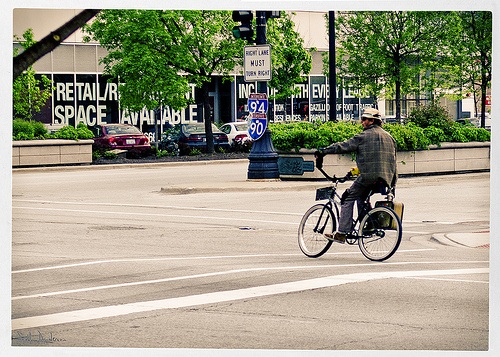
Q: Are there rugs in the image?
A: No, there are no rugs.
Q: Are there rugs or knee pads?
A: No, there are no rugs or knee pads.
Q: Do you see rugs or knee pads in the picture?
A: No, there are no rugs or knee pads.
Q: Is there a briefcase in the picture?
A: Yes, there is a briefcase.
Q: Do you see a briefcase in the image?
A: Yes, there is a briefcase.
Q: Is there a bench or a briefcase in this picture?
A: Yes, there is a briefcase.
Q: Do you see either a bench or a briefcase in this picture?
A: Yes, there is a briefcase.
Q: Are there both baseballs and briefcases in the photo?
A: No, there is a briefcase but no baseballs.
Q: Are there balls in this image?
A: No, there are no balls.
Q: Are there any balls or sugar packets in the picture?
A: No, there are no balls or sugar packets.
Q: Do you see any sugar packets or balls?
A: No, there are no balls or sugar packets.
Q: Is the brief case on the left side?
A: No, the brief case is on the right of the image.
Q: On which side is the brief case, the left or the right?
A: The brief case is on the right of the image.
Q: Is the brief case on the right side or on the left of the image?
A: The brief case is on the right of the image.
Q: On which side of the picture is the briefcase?
A: The briefcase is on the right of the image.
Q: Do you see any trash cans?
A: No, there are no trash cans.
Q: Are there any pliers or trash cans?
A: No, there are no trash cans or pliers.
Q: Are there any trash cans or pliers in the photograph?
A: No, there are no trash cans or pliers.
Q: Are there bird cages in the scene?
A: No, there are no bird cages.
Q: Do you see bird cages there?
A: No, there are no bird cages.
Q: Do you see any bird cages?
A: No, there are no bird cages.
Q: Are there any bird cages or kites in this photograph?
A: No, there are no bird cages or kites.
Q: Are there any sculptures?
A: No, there are no sculptures.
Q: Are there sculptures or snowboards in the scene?
A: No, there are no sculptures or snowboards.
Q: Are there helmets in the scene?
A: No, there are no helmets.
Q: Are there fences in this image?
A: No, there are no fences.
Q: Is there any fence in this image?
A: No, there are no fences.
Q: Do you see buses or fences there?
A: No, there are no fences or buses.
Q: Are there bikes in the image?
A: Yes, there is a bike.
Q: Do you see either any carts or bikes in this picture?
A: Yes, there is a bike.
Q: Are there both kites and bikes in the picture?
A: No, there is a bike but no kites.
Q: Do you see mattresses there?
A: No, there are no mattresses.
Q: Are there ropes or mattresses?
A: No, there are no mattresses or ropes.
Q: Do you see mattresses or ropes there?
A: No, there are no mattresses or ropes.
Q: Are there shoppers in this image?
A: No, there are no shoppers.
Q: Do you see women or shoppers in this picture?
A: No, there are no shoppers or women.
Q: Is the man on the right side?
A: Yes, the man is on the right of the image.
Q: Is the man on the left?
A: No, the man is on the right of the image.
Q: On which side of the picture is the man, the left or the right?
A: The man is on the right of the image.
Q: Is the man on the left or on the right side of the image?
A: The man is on the right of the image.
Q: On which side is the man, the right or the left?
A: The man is on the right of the image.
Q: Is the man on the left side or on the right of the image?
A: The man is on the right of the image.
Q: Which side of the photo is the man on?
A: The man is on the right of the image.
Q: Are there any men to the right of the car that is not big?
A: Yes, there is a man to the right of the car.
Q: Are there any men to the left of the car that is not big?
A: No, the man is to the right of the car.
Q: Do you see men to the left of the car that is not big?
A: No, the man is to the right of the car.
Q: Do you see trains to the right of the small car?
A: No, there is a man to the right of the car.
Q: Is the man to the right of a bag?
A: No, the man is to the right of the car.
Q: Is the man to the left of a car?
A: No, the man is to the right of a car.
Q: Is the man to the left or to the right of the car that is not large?
A: The man is to the right of the car.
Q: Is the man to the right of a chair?
A: No, the man is to the right of the car.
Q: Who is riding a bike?
A: The man is riding a bike.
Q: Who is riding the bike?
A: The man is riding a bike.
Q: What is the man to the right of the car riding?
A: The man is riding a bike.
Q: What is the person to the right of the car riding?
A: The man is riding a bike.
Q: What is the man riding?
A: The man is riding a bike.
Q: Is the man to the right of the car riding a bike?
A: Yes, the man is riding a bike.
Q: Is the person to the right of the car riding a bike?
A: Yes, the man is riding a bike.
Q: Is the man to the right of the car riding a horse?
A: No, the man is riding a bike.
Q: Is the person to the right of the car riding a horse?
A: No, the man is riding a bike.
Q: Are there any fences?
A: No, there are no fences.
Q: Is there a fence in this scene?
A: No, there are no fences.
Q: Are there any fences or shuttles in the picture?
A: No, there are no fences or shuttles.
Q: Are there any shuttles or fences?
A: No, there are no fences or shuttles.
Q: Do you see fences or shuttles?
A: No, there are no fences or shuttles.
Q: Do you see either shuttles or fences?
A: No, there are no fences or shuttles.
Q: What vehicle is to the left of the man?
A: The vehicle is a car.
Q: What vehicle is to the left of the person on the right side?
A: The vehicle is a car.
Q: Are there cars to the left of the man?
A: Yes, there is a car to the left of the man.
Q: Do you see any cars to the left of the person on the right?
A: Yes, there is a car to the left of the man.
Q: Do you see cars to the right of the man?
A: No, the car is to the left of the man.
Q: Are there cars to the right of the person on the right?
A: No, the car is to the left of the man.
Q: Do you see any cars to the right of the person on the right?
A: No, the car is to the left of the man.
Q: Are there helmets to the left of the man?
A: No, there is a car to the left of the man.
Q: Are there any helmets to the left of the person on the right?
A: No, there is a car to the left of the man.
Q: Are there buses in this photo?
A: No, there are no buses.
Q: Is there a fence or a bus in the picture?
A: No, there are no buses or fences.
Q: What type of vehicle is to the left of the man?
A: The vehicle is a car.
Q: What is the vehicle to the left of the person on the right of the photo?
A: The vehicle is a car.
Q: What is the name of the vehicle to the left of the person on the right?
A: The vehicle is a car.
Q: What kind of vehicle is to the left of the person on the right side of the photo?
A: The vehicle is a car.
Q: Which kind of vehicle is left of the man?
A: The vehicle is a car.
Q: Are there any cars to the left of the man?
A: Yes, there is a car to the left of the man.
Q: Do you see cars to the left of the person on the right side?
A: Yes, there is a car to the left of the man.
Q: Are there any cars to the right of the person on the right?
A: No, the car is to the left of the man.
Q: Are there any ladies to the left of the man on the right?
A: No, there is a car to the left of the man.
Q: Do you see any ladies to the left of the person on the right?
A: No, there is a car to the left of the man.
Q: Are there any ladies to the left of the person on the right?
A: No, there is a car to the left of the man.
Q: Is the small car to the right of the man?
A: No, the car is to the left of the man.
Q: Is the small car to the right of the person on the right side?
A: No, the car is to the left of the man.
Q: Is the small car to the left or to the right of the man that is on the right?
A: The car is to the left of the man.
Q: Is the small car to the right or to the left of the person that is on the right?
A: The car is to the left of the man.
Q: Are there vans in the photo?
A: No, there are no vans.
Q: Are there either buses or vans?
A: No, there are no vans or buses.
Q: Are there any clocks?
A: No, there are no clocks.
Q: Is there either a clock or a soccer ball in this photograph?
A: No, there are no clocks or soccer balls.